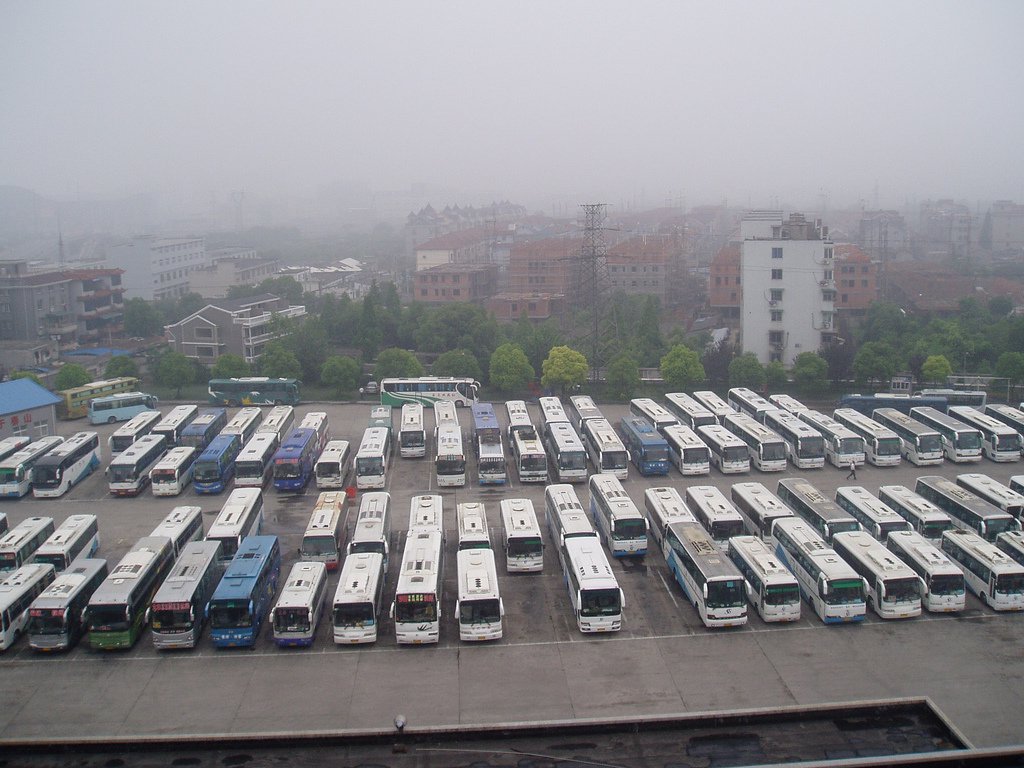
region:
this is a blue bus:
[188, 518, 299, 661]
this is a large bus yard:
[14, 373, 1017, 656]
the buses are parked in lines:
[10, 366, 1017, 661]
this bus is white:
[552, 534, 635, 648]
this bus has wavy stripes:
[355, 360, 502, 417]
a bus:
[560, 541, 638, 640]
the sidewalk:
[496, 664, 604, 706]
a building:
[740, 236, 827, 367]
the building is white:
[739, 245, 816, 363]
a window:
[765, 256, 792, 310]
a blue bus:
[212, 542, 258, 647]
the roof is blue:
[12, 377, 35, 404]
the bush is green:
[361, 301, 420, 356]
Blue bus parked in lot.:
[227, 535, 278, 657]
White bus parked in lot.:
[405, 528, 438, 633]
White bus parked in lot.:
[455, 552, 513, 651]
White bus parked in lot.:
[558, 531, 620, 630]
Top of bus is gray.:
[670, 518, 738, 592]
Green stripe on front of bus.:
[833, 574, 872, 595]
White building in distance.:
[745, 220, 845, 410]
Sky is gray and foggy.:
[27, 50, 972, 203]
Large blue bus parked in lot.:
[271, 416, 314, 512]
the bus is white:
[272, 559, 321, 643]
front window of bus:
[273, 606, 311, 627]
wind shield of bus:
[397, 603, 432, 622]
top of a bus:
[453, 551, 493, 603]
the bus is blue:
[210, 533, 281, 647]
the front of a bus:
[207, 602, 249, 648]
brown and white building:
[165, 303, 238, 368]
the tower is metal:
[576, 205, 608, 327]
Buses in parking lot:
[27, 407, 973, 635]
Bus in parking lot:
[547, 535, 639, 634]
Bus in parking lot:
[246, 544, 330, 647]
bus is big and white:
[457, 545, 502, 641]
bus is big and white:
[558, 532, 628, 632]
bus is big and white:
[589, 472, 650, 555]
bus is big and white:
[538, 476, 595, 544]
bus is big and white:
[498, 496, 546, 576]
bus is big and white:
[662, 520, 754, 632]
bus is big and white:
[732, 536, 802, 623]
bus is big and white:
[833, 527, 922, 616]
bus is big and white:
[890, 529, 960, 612]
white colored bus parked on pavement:
[447, 547, 501, 647]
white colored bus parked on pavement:
[571, 523, 619, 634]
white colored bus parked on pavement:
[580, 453, 645, 552]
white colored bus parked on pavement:
[494, 485, 551, 577]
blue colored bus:
[203, 528, 281, 647]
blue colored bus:
[270, 422, 312, 493]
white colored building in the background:
[722, 231, 839, 367]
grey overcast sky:
[8, 10, 1023, 216]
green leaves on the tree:
[544, 366, 592, 386]